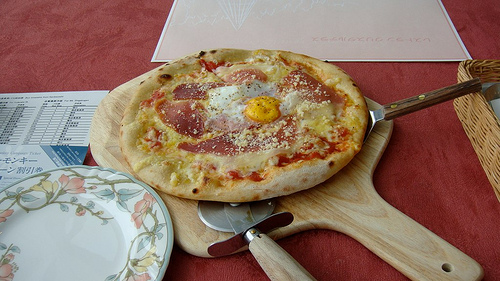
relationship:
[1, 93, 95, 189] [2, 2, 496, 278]
paper on table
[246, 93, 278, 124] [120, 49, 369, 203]
egg yolk on pizza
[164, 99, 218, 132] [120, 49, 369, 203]
ham on pizza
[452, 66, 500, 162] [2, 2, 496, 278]
basket on table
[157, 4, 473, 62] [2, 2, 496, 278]
poster on table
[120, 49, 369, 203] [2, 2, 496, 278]
pizza on table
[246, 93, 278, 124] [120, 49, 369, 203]
egg yolk on top of pizza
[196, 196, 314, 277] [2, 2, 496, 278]
pizza cutter on table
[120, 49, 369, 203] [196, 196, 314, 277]
pizza on top of pizza cutter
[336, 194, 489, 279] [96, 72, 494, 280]
handle of tray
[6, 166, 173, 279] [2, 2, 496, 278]
plate on table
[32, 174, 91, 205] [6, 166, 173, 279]
flowers on plate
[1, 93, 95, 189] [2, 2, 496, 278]
paper on top of table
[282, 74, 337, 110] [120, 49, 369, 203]
meat on pizza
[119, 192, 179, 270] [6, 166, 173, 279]
floral pattern on plate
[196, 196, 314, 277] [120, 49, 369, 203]
pizza cutter under pizza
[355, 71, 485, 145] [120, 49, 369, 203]
spatula wedged under pizza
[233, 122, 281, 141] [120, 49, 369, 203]
cheese on pizza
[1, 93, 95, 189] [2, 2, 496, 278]
menu on table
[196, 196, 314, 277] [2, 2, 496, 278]
pizza cutter on pizza board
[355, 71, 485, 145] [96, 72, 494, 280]
pizza server on pizza board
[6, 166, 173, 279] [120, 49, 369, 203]
plate next to pizza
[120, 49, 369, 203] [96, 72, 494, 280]
pizza on board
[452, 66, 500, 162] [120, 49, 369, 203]
basket next to pizza